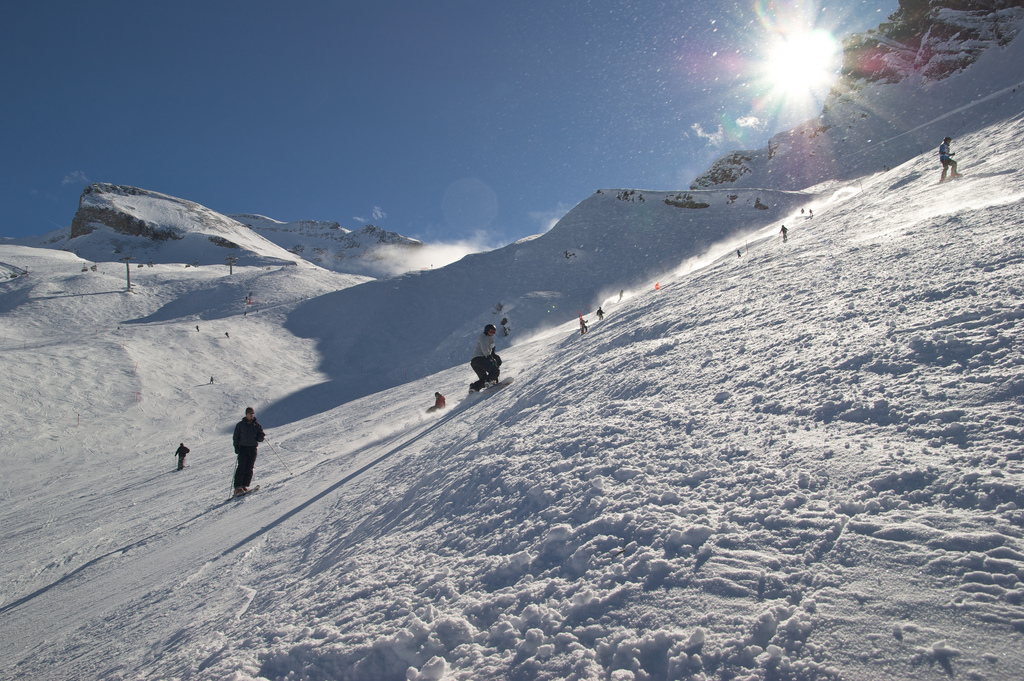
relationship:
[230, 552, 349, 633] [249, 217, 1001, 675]
snow on ground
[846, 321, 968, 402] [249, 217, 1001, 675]
snow on ground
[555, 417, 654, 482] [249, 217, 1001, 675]
snow on ground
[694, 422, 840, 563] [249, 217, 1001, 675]
snow on ground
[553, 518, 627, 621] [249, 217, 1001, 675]
snow on ground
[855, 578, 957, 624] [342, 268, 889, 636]
snow on ground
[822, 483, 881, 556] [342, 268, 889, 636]
snow on ground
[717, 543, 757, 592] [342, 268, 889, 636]
snow on ground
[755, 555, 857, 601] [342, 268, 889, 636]
snow on ground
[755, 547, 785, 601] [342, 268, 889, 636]
snow on ground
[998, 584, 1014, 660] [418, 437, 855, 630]
snow on ground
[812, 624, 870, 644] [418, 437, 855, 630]
snow on ground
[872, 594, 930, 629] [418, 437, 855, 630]
snow on ground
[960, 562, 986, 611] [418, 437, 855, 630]
snow on ground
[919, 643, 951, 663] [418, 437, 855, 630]
snow on ground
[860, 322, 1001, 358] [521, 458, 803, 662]
snow on ground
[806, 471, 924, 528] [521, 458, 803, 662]
snow on ground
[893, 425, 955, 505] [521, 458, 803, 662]
snow on ground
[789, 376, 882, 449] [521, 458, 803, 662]
snow on ground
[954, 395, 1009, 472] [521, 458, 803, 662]
snow on ground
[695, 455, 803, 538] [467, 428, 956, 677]
snow on ground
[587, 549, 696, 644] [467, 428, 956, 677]
snow on ground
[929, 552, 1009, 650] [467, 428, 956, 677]
snow on ground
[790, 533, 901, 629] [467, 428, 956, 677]
snow on ground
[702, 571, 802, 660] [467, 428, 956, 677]
snow on ground